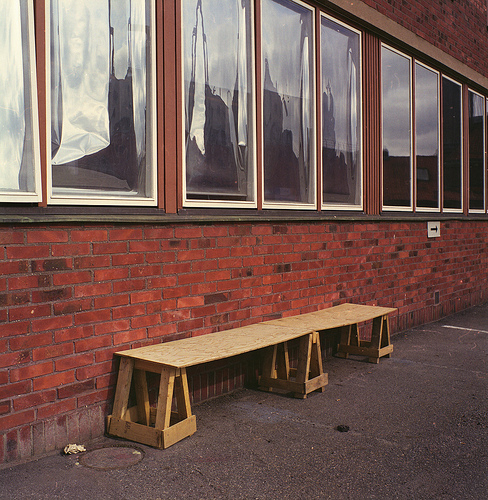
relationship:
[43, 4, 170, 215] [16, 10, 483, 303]
window on building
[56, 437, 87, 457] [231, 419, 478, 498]
trash on concrete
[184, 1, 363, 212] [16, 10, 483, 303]
window on building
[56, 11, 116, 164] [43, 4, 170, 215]
curtain on window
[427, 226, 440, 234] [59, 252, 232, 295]
arrow on wall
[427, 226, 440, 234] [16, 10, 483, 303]
arrow on building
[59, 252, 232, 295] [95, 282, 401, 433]
wall behind bench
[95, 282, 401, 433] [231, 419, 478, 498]
bench on concrete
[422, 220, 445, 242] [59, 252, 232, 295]
sign on wall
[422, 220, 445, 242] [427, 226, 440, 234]
sign has arrow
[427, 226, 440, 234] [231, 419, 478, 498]
arrow above concrete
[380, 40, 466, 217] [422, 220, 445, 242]
window above sign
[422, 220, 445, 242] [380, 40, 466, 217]
sign bellow window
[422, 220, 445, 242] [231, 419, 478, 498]
sign above concrete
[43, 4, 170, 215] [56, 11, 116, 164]
window has curtain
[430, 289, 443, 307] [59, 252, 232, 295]
vent in wall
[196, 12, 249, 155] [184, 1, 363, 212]
curtain in window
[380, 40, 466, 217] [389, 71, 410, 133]
window reflecting sky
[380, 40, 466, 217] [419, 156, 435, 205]
window reflecting building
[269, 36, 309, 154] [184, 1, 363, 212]
curtain in window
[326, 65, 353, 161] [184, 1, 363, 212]
curtain in window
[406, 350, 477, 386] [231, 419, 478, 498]
crack in concrete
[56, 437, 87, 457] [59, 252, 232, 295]
trash against wall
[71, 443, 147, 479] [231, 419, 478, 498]
cover in concrete